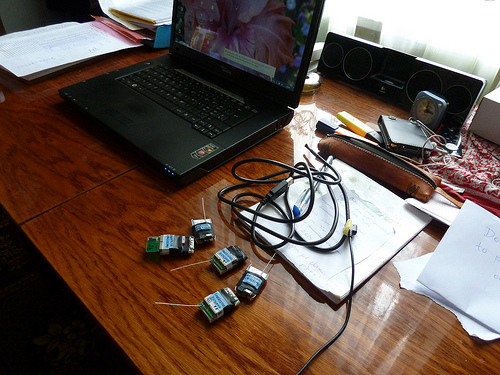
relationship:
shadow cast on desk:
[176, 128, 298, 210] [2, 34, 498, 374]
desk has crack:
[2, 34, 498, 374] [13, 159, 150, 226]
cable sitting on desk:
[212, 140, 351, 262] [2, 34, 498, 374]